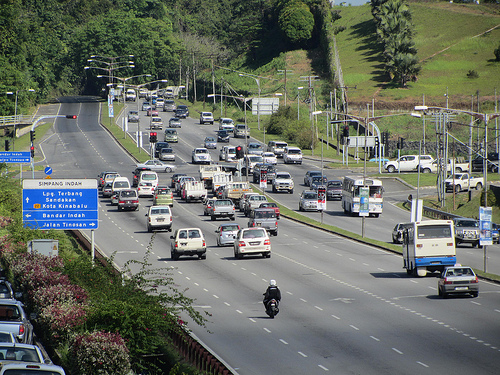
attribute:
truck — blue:
[403, 219, 456, 276]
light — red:
[25, 108, 78, 178]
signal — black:
[149, 132, 156, 160]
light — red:
[149, 131, 156, 135]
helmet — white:
[263, 275, 281, 285]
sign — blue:
[44, 166, 53, 176]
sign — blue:
[18, 181, 100, 237]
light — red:
[130, 197, 140, 202]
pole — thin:
[88, 228, 97, 270]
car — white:
[144, 195, 176, 242]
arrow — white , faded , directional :
[332, 295, 356, 306]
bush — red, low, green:
[30, 267, 102, 337]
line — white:
[231, 306, 243, 317]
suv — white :
[231, 224, 276, 266]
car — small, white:
[433, 263, 475, 298]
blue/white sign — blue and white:
[20, 175, 103, 230]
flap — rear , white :
[415, 263, 434, 281]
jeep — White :
[231, 216, 275, 256]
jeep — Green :
[148, 187, 176, 209]